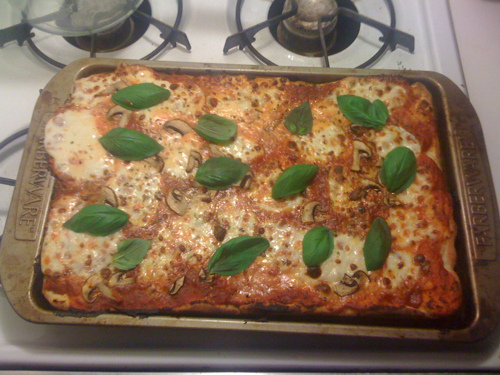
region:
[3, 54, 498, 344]
pizza in metal pan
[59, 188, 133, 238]
green leaf on top of pizza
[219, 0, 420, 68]
black burner on top of stove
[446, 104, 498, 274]
metal pan brand name on edge of pan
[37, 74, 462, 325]
cooked white cheese on top of pizza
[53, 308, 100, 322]
dark burned crust on edge of metal pan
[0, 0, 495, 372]
top of white stove with two visible black burners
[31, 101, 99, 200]
white cheese melted onto the side of the metal pan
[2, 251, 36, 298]
brown burn marks ingrained on the edge of metal pan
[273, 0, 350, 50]
center of black metal burner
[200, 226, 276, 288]
A basil leaf on pizza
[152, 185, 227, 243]
mushrooms on a homemade pizza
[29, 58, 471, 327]
Home made pizza in a pan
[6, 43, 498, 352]
A baking pan containing an entree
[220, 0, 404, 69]
A burner on a kitchen stove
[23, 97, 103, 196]
Cheese overflowing onto a pan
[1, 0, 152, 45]
Part of a clear dish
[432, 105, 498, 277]
the word farberware printed on a pan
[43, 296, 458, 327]
slightly burnt edge of a pizza crust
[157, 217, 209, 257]
A section of melted cheese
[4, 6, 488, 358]
pizza on a stove top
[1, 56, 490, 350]
pizza on a cookie sheet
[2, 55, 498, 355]
cookie sheet that pizza is on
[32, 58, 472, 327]
pizza with fresh basil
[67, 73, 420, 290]
fresh basil on pizza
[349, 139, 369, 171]
mushroom on pizza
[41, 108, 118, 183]
melted cheese on top of pizza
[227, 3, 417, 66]
gas burner on stove top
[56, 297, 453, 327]
burnt cheese on edge of pizza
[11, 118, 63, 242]
logo on cookie sheet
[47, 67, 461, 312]
a lasagna with cheese and basil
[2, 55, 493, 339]
a lasagna in a metal tray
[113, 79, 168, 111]
a leaf of basil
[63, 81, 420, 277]
basil leaves on a lasagna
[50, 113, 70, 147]
bubbles in melted cheese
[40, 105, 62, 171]
melted cheese on a metal tray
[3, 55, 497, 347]
a metal tray on the burner of an oven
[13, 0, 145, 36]
a glass plate on a burner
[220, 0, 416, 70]
an oven burner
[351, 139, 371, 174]
a slice of mushroom in a lasagna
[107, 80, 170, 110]
fresh picked basil leaf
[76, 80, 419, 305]
canned mushroom topping for the pasta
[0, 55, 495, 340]
Pan of baked lasagna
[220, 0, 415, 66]
gas stove burner and grate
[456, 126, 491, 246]
Name of pan, "Farberware"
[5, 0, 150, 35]
unidentifiable plastic lid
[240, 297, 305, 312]
Overcooked part of pasta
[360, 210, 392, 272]
fresh basil leaf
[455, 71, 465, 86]
Scratch on the stove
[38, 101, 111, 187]
Overflowing melted cheese